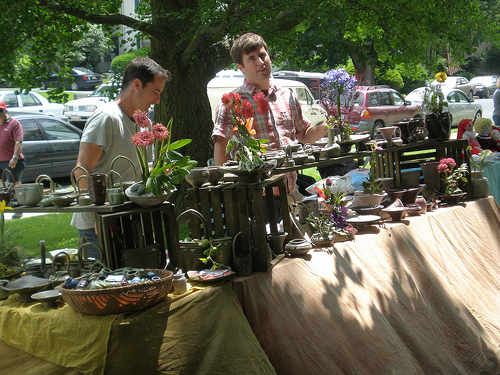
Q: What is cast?
A: Shadow.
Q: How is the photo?
A: Clear.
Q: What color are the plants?
A: Green.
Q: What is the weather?
A: Sunny.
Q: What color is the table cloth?
A: Brown.